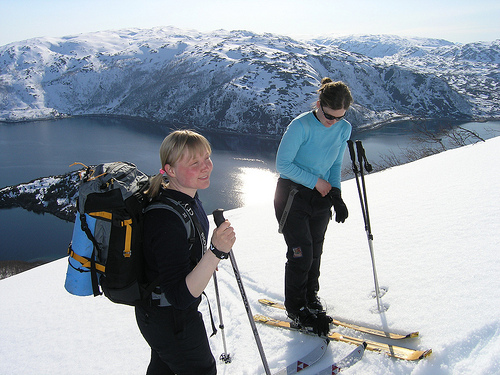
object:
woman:
[131, 129, 234, 375]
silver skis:
[271, 338, 330, 374]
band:
[159, 168, 166, 174]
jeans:
[272, 177, 330, 310]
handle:
[212, 208, 225, 228]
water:
[4, 144, 31, 172]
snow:
[0, 136, 500, 375]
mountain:
[0, 26, 499, 139]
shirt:
[273, 110, 352, 190]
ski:
[249, 313, 433, 360]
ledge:
[0, 252, 70, 282]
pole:
[357, 160, 380, 311]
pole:
[228, 249, 271, 375]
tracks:
[421, 315, 497, 375]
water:
[94, 128, 141, 160]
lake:
[0, 113, 500, 265]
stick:
[211, 255, 233, 365]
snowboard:
[252, 297, 418, 341]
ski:
[257, 297, 419, 341]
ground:
[0, 134, 500, 375]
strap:
[85, 210, 133, 257]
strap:
[66, 246, 106, 272]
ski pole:
[353, 163, 380, 295]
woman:
[272, 77, 353, 335]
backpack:
[62, 158, 198, 307]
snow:
[1, 24, 500, 136]